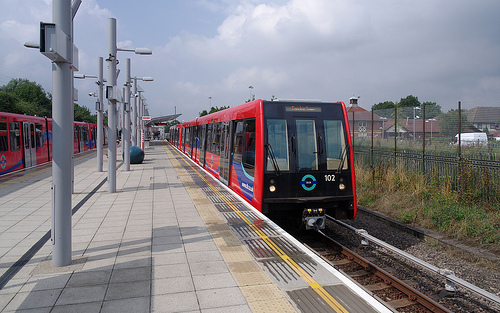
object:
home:
[344, 97, 385, 137]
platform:
[22, 0, 86, 266]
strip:
[165, 136, 350, 311]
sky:
[0, 0, 500, 120]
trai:
[168, 98, 357, 229]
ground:
[360, 95, 408, 130]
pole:
[50, 1, 74, 266]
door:
[23, 121, 37, 168]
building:
[345, 94, 388, 140]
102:
[324, 174, 335, 181]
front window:
[325, 120, 348, 171]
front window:
[297, 117, 317, 173]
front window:
[266, 119, 288, 173]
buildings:
[467, 105, 500, 132]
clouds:
[388, 1, 498, 88]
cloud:
[162, 0, 365, 82]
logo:
[299, 174, 319, 191]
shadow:
[1, 216, 270, 277]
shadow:
[70, 179, 220, 194]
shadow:
[125, 165, 198, 171]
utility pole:
[24, 0, 82, 267]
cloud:
[0, 0, 108, 52]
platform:
[0, 145, 395, 313]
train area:
[0, 138, 395, 313]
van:
[450, 132, 489, 148]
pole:
[106, 16, 116, 193]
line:
[288, 257, 330, 301]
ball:
[122, 146, 146, 164]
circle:
[299, 174, 318, 191]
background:
[0, 0, 500, 138]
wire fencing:
[421, 104, 457, 155]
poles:
[394, 107, 399, 174]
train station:
[1, 141, 394, 313]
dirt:
[365, 250, 383, 258]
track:
[313, 216, 494, 313]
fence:
[351, 102, 498, 206]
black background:
[270, 174, 350, 195]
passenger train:
[0, 110, 108, 178]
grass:
[384, 170, 497, 227]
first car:
[197, 99, 358, 229]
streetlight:
[111, 48, 154, 54]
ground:
[0, 138, 389, 311]